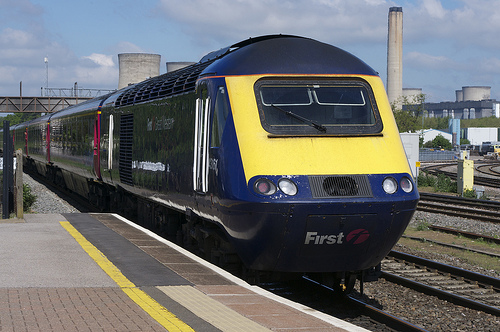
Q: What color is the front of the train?
A: Yellow and blue.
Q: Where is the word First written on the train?
A: Front of the train.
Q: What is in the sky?
A: Clouds.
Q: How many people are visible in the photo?
A: None.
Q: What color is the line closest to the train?
A: White.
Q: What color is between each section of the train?
A: Red.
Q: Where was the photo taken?
A: At a train station.